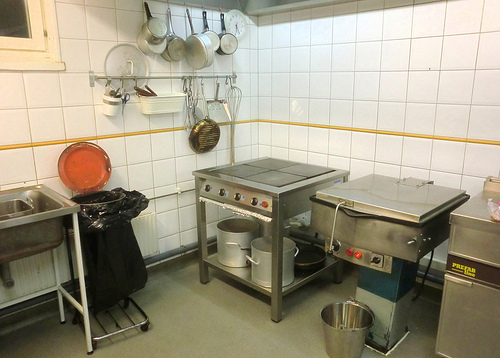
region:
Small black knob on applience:
[325, 235, 345, 255]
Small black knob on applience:
[366, 245, 385, 267]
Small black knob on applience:
[244, 191, 261, 209]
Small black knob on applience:
[225, 189, 246, 209]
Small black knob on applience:
[210, 185, 231, 207]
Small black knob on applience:
[202, 180, 213, 195]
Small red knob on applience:
[260, 195, 277, 222]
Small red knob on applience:
[340, 240, 357, 260]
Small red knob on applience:
[354, 245, 364, 261]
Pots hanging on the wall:
[121, 2, 261, 79]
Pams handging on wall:
[132, 2, 247, 87]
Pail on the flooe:
[312, 288, 386, 356]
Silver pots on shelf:
[209, 207, 252, 286]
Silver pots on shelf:
[242, 229, 291, 301]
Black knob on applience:
[362, 252, 380, 282]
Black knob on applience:
[319, 237, 340, 249]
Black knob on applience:
[247, 189, 258, 219]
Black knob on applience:
[227, 186, 244, 212]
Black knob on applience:
[210, 180, 229, 207]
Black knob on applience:
[201, 179, 221, 209]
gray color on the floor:
[180, 308, 246, 331]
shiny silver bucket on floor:
[311, 291, 381, 346]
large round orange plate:
[51, 140, 121, 190]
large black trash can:
[75, 181, 172, 289]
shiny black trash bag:
[86, 194, 161, 236]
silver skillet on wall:
[180, 116, 228, 156]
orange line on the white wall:
[287, 120, 413, 140]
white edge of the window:
[11, 26, 88, 74]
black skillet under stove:
[285, 234, 337, 279]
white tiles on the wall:
[306, 55, 392, 102]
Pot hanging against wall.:
[214, 15, 244, 73]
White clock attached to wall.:
[219, 6, 268, 47]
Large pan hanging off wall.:
[188, 18, 217, 88]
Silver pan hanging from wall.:
[164, 35, 186, 72]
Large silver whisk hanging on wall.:
[221, 86, 257, 168]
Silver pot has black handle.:
[144, 14, 168, 44]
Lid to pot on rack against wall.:
[101, 42, 155, 121]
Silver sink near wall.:
[9, 173, 79, 304]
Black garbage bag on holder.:
[64, 182, 166, 283]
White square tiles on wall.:
[319, 53, 403, 111]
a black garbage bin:
[62, 194, 152, 312]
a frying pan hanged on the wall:
[187, 82, 228, 154]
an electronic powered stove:
[185, 137, 358, 322]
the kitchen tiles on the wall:
[259, 16, 499, 151]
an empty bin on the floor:
[312, 295, 380, 355]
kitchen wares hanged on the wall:
[91, 7, 258, 153]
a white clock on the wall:
[222, 7, 249, 40]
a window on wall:
[0, 0, 77, 72]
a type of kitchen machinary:
[311, 154, 472, 356]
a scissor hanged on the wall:
[119, 78, 133, 119]